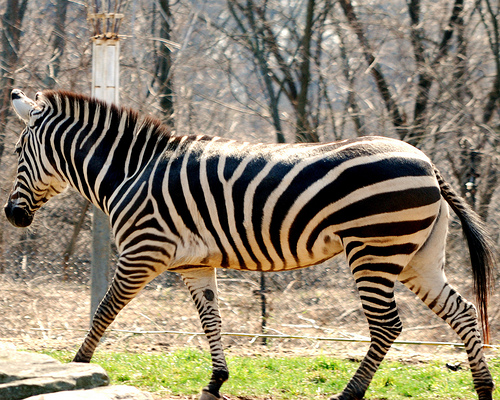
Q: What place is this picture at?
A: It is at the zoo.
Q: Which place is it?
A: It is a zoo.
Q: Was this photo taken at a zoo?
A: Yes, it was taken in a zoo.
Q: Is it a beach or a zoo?
A: It is a zoo.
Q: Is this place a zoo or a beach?
A: It is a zoo.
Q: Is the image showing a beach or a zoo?
A: It is showing a zoo.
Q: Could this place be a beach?
A: No, it is a zoo.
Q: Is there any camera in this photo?
A: Yes, there is a camera.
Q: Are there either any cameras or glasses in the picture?
A: Yes, there is a camera.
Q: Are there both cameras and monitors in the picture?
A: No, there is a camera but no monitors.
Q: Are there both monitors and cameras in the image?
A: No, there is a camera but no monitors.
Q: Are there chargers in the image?
A: No, there are no chargers.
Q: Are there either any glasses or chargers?
A: No, there are no chargers or glasses.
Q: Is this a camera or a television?
A: This is a camera.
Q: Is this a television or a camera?
A: This is a camera.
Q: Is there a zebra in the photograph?
A: Yes, there is a zebra.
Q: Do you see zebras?
A: Yes, there is a zebra.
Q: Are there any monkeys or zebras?
A: Yes, there is a zebra.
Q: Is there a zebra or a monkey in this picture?
A: Yes, there is a zebra.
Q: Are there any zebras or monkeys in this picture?
A: Yes, there is a zebra.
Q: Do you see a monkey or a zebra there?
A: Yes, there is a zebra.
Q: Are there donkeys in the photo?
A: No, there are no donkeys.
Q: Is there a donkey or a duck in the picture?
A: No, there are no donkeys or ducks.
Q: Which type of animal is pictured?
A: The animal is a zebra.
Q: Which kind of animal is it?
A: The animal is a zebra.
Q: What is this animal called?
A: That is a zebra.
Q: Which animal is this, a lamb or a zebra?
A: That is a zebra.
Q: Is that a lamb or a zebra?
A: That is a zebra.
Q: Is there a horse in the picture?
A: No, there are no horses.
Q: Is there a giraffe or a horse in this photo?
A: No, there are no horses or giraffes.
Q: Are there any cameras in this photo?
A: Yes, there is a camera.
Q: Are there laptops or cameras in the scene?
A: Yes, there is a camera.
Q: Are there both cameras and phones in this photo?
A: No, there is a camera but no phones.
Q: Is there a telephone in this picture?
A: No, there are no phones.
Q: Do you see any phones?
A: No, there are no phones.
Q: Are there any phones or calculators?
A: No, there are no phones or calculators.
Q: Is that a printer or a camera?
A: That is a camera.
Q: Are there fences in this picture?
A: Yes, there is a fence.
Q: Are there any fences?
A: Yes, there is a fence.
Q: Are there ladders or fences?
A: Yes, there is a fence.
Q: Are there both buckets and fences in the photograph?
A: No, there is a fence but no buckets.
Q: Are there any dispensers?
A: No, there are no dispensers.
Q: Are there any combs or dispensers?
A: No, there are no dispensers or combs.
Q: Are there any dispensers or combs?
A: No, there are no dispensers or combs.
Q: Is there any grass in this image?
A: Yes, there is grass.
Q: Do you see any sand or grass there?
A: Yes, there is grass.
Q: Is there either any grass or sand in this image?
A: Yes, there is grass.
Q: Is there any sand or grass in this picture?
A: Yes, there is grass.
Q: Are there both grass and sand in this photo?
A: No, there is grass but no sand.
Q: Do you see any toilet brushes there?
A: No, there are no toilet brushes.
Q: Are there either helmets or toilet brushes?
A: No, there are no toilet brushes or helmets.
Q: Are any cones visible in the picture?
A: No, there are no cones.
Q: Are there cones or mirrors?
A: No, there are no cones or mirrors.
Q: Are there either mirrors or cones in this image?
A: No, there are no cones or mirrors.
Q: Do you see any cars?
A: No, there are no cars.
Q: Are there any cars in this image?
A: No, there are no cars.